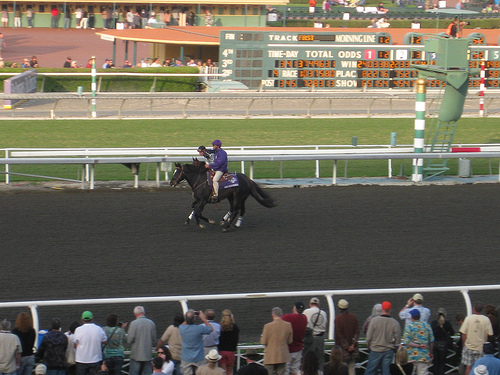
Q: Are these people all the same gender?
A: No, they are both male and female.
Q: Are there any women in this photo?
A: Yes, there is a woman.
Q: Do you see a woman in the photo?
A: Yes, there is a woman.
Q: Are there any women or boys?
A: Yes, there is a woman.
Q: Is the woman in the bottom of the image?
A: Yes, the woman is in the bottom of the image.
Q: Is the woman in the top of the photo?
A: No, the woman is in the bottom of the image.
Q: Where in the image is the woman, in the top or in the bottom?
A: The woman is in the bottom of the image.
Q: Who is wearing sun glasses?
A: The woman is wearing sun glasses.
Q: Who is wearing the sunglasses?
A: The woman is wearing sun glasses.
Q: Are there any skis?
A: No, there are no skis.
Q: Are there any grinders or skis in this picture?
A: No, there are no skis or grinders.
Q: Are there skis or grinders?
A: No, there are no skis or grinders.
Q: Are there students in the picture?
A: No, there are no students.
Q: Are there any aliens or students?
A: No, there are no students or aliens.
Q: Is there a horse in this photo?
A: Yes, there is a horse.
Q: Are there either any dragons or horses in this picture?
A: Yes, there is a horse.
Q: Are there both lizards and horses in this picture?
A: No, there is a horse but no lizards.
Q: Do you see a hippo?
A: No, there are no hippoes.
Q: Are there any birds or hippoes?
A: No, there are no hippoes or birds.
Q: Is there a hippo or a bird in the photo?
A: No, there are no hippoes or birds.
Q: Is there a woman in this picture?
A: Yes, there is a woman.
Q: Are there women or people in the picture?
A: Yes, there is a woman.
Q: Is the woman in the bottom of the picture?
A: Yes, the woman is in the bottom of the image.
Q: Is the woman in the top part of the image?
A: No, the woman is in the bottom of the image.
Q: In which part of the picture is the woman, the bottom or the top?
A: The woman is in the bottom of the image.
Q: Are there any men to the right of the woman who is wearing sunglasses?
A: Yes, there is a man to the right of the woman.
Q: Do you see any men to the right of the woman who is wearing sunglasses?
A: Yes, there is a man to the right of the woman.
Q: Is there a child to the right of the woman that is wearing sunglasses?
A: No, there is a man to the right of the woman.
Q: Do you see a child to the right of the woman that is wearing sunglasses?
A: No, there is a man to the right of the woman.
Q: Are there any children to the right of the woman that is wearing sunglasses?
A: No, there is a man to the right of the woman.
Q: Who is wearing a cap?
A: The man is wearing a cap.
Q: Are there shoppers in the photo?
A: No, there are no shoppers.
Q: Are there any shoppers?
A: No, there are no shoppers.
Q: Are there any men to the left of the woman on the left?
A: Yes, there is a man to the left of the woman.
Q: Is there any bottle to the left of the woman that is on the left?
A: No, there is a man to the left of the woman.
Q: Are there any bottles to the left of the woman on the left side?
A: No, there is a man to the left of the woman.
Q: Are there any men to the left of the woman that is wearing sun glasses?
A: Yes, there is a man to the left of the woman.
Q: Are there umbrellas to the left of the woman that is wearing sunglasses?
A: No, there is a man to the left of the woman.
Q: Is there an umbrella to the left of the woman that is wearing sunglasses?
A: No, there is a man to the left of the woman.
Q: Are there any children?
A: No, there are no children.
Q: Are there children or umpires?
A: No, there are no children or umpires.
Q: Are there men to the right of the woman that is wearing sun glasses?
A: Yes, there is a man to the right of the woman.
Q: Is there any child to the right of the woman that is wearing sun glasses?
A: No, there is a man to the right of the woman.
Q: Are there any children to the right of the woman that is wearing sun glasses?
A: No, there is a man to the right of the woman.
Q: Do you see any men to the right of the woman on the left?
A: Yes, there is a man to the right of the woman.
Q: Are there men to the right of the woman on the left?
A: Yes, there is a man to the right of the woman.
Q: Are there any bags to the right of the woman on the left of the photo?
A: No, there is a man to the right of the woman.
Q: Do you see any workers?
A: No, there are no workers.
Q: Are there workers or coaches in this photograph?
A: No, there are no workers or coaches.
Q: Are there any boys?
A: No, there are no boys.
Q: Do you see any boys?
A: No, there are no boys.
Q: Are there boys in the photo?
A: No, there are no boys.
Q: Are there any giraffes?
A: No, there are no giraffes.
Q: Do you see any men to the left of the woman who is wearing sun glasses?
A: Yes, there is a man to the left of the woman.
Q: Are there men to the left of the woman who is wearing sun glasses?
A: Yes, there is a man to the left of the woman.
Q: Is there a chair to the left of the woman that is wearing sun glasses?
A: No, there is a man to the left of the woman.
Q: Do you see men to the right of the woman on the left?
A: Yes, there is a man to the right of the woman.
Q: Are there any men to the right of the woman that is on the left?
A: Yes, there is a man to the right of the woman.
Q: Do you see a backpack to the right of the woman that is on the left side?
A: No, there is a man to the right of the woman.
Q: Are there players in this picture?
A: No, there are no players.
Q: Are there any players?
A: No, there are no players.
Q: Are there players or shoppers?
A: No, there are no players or shoppers.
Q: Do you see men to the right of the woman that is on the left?
A: Yes, there is a man to the right of the woman.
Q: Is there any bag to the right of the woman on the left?
A: No, there is a man to the right of the woman.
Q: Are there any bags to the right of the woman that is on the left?
A: No, there is a man to the right of the woman.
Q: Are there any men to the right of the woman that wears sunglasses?
A: Yes, there is a man to the right of the woman.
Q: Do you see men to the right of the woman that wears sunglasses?
A: Yes, there is a man to the right of the woman.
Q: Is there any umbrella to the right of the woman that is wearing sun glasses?
A: No, there is a man to the right of the woman.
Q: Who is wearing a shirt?
A: The man is wearing a shirt.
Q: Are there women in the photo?
A: Yes, there is a woman.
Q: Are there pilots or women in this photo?
A: Yes, there is a woman.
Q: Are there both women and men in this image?
A: Yes, there are both a woman and a man.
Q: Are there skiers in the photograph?
A: No, there are no skiers.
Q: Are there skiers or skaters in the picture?
A: No, there are no skiers or skaters.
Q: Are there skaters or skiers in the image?
A: No, there are no skiers or skaters.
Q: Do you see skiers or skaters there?
A: No, there are no skiers or skaters.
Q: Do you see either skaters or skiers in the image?
A: No, there are no skiers or skaters.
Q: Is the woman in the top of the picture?
A: No, the woman is in the bottom of the image.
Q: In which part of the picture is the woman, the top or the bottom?
A: The woman is in the bottom of the image.